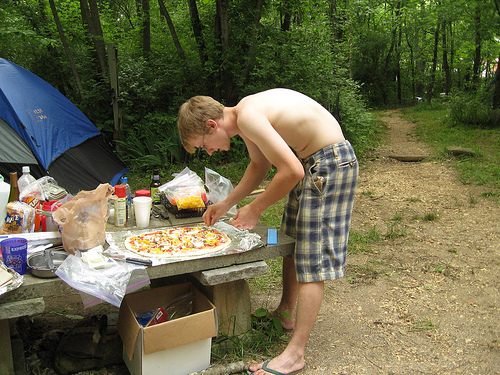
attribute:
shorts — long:
[270, 139, 374, 306]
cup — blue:
[1, 236, 31, 275]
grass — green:
[357, 100, 496, 194]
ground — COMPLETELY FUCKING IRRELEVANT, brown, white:
[393, 99, 489, 158]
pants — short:
[269, 147, 346, 232]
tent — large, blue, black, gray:
[0, 52, 142, 212]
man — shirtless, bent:
[170, 85, 369, 373]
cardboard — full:
[120, 284, 220, 367]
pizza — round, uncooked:
[130, 237, 245, 272]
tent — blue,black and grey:
[2, 55, 136, 195]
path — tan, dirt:
[352, 101, 499, 374]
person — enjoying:
[143, 66, 440, 339]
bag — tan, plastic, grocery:
[50, 182, 113, 253]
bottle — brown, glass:
[151, 167, 160, 204]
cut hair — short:
[156, 87, 220, 155]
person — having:
[181, 75, 377, 369]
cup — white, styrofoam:
[133, 189, 156, 224]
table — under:
[0, 205, 291, 361]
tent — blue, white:
[0, 60, 122, 201]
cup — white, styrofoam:
[133, 193, 160, 223]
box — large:
[115, 280, 220, 372]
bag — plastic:
[61, 252, 135, 296]